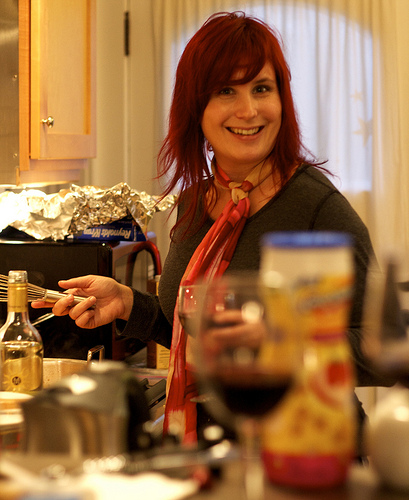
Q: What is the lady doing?
A: Cooking.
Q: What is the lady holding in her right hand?
A: A whisk.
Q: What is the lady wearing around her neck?
A: A scarf.